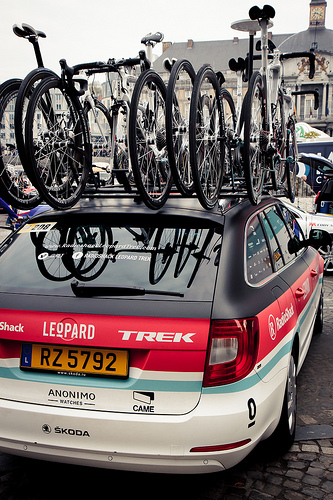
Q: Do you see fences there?
A: No, there are no fences.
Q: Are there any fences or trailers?
A: No, there are no fences or trailers.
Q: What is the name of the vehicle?
A: The vehicle is a car.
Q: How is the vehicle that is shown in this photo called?
A: The vehicle is a car.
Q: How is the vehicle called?
A: The vehicle is a car.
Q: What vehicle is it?
A: The vehicle is a car.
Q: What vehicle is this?
A: This is a car.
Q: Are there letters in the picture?
A: Yes, there are letters.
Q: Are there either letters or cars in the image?
A: Yes, there are letters.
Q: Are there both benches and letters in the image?
A: No, there are letters but no benches.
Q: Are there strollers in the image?
A: No, there are no strollers.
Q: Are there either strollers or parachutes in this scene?
A: No, there are no strollers or parachutes.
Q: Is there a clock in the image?
A: Yes, there is a clock.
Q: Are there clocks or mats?
A: Yes, there is a clock.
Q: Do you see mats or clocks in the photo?
A: Yes, there is a clock.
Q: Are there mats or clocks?
A: Yes, there is a clock.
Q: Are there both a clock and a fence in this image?
A: No, there is a clock but no fences.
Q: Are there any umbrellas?
A: No, there are no umbrellas.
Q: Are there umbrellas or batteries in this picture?
A: No, there are no umbrellas or batteries.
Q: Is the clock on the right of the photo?
A: Yes, the clock is on the right of the image.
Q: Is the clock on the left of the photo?
A: No, the clock is on the right of the image.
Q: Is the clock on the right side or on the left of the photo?
A: The clock is on the right of the image.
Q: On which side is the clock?
A: The clock is on the right of the image.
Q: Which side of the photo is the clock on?
A: The clock is on the right of the image.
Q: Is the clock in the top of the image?
A: Yes, the clock is in the top of the image.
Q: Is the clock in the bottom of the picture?
A: No, the clock is in the top of the image.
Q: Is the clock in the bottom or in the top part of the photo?
A: The clock is in the top of the image.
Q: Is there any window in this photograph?
A: Yes, there is a window.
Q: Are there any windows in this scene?
A: Yes, there is a window.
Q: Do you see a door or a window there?
A: Yes, there is a window.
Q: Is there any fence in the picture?
A: No, there are no fences.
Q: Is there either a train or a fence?
A: No, there are no fences or trains.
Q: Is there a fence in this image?
A: No, there are no fences.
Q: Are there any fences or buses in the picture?
A: No, there are no fences or buses.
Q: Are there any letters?
A: Yes, there are letters.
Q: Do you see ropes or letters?
A: Yes, there are letters.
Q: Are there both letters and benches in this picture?
A: No, there are letters but no benches.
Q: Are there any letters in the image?
A: Yes, there are letters.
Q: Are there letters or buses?
A: Yes, there are letters.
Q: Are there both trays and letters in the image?
A: No, there are letters but no trays.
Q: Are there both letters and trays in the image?
A: No, there are letters but no trays.